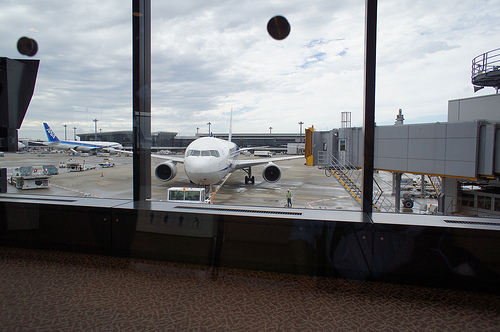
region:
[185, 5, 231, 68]
this is the sky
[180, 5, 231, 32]
the sky is blue in color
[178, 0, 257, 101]
the sky has clouds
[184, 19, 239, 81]
the clouds are white in color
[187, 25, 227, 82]
the clouds are big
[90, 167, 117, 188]
this is the runway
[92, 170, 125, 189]
the runway is clean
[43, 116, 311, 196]
this is an airplane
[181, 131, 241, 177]
the plane is big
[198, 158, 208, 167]
the plane is white in color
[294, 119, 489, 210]
a loading bridge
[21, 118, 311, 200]
two aircrafts in airport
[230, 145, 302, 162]
right wing of plane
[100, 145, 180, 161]
left wing of plane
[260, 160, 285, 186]
the right engine of plane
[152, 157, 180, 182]
the left engine of plane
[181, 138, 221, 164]
windows of cockpit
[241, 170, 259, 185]
the right wheel of plane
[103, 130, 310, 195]
the plane is white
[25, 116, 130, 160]
a blue and white plane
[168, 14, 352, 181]
large glass in window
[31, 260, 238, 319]
brown and black carpet on the floor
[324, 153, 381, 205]
yellow and gray steps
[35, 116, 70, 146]
blue wings on the plane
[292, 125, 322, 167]
yellow and brown door on conveyor belt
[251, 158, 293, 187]
large wing on plane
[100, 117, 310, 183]
large white plane on tarmac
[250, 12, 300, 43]
black circle on glass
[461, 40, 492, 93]
tall balcony over building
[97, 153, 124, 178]
white truck on the tarmac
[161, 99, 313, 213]
A plane at an airport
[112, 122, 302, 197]
The plane is not in the air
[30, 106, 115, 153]
This plane is white with a blue stripe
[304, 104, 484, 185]
This hooks to plane for passengers to board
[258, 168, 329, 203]
It has rained today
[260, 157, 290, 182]
An engine on the plane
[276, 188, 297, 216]
A man on the tarmac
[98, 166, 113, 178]
An orange traffic cone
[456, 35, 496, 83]
A walkway on the watchtower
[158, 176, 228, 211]
This taxis the plane to the runway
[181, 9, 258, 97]
this is the sky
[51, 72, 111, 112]
the sky is blue in color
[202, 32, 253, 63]
these are the clouds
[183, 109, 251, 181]
this is a jet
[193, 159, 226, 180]
the jet is white in color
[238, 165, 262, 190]
this is the wheel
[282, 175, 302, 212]
this is a person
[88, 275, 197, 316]
this is the floor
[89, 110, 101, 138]
this is a pole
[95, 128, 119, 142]
this is a building